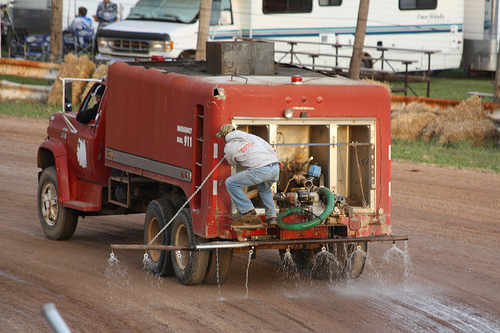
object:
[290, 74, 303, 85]
light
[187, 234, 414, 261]
watering system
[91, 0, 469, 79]
rv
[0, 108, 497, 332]
race track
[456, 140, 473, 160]
ground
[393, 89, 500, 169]
grass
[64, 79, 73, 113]
mirror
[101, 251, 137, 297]
water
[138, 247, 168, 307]
water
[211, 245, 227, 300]
water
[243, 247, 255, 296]
water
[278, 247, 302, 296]
water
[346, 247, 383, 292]
water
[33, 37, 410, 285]
truck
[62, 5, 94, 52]
man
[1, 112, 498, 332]
road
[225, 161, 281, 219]
jeans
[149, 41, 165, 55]
headlight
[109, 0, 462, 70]
camper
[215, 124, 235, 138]
brown cap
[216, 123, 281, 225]
man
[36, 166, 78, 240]
tire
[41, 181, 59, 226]
metal rim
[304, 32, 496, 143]
rail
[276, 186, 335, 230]
hose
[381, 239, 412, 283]
water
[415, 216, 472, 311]
dirt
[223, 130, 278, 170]
hoodie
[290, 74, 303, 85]
indicator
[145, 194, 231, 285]
wheels